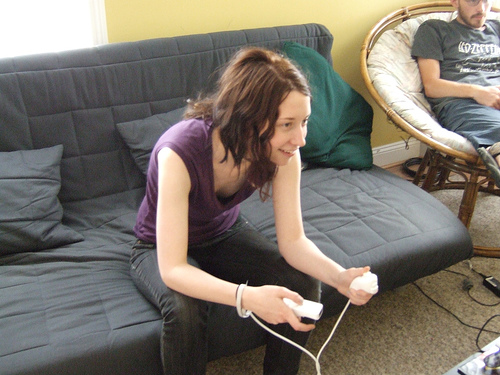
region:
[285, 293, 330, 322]
a white game controller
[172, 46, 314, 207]
a girl's brown hair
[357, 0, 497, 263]
part of a large chair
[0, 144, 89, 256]
part of a black pillow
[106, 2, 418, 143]
part of a yellow wall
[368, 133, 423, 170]
part of a white floor trim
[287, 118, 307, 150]
the nose of a girl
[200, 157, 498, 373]
a section of carpet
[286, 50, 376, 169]
part of a green pillow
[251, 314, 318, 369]
a long white cord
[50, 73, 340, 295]
Sofa is black color.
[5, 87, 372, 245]
Three pillows in couch.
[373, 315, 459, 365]
Floor is brown color.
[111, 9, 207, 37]
Wall is brown color.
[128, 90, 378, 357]
One girl is sitting in couch.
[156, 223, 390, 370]
Girl is holding wii in hand.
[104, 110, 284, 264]
Girl is wearing purple shirt.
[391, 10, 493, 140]
One boy is sitting in chair.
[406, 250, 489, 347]
Wires are black color.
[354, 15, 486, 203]
Chair is brown color.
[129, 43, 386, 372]
a girl wearing purple play the Wii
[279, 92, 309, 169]
the face of a girl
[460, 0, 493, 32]
the face of a man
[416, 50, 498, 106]
the arm of a man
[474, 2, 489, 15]
the nose of a man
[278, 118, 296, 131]
the eye of a girl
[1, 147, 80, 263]
a pillow on a couch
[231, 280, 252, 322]
a bracelet on a wrist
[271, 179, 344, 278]
the arm of a girl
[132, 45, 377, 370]
a woman sitting on a couch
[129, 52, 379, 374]
a woman playing a video game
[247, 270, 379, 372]
a Wii video game controller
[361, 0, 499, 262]
a man sitting in a chair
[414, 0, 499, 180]
a man playing a video game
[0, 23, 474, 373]
a dark grey couch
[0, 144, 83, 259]
a grey throw pillow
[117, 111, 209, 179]
a grey throw pillow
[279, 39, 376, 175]
a green throw pillow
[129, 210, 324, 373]
a pair of black jeans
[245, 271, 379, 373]
Wii game controllers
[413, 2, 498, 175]
A young man sitting in a chair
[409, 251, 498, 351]
Various cables lying on the floor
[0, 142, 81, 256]
A gray pillow on a couch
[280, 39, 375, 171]
A large green pillow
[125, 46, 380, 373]
A young woman playing a video game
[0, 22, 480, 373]
A gray couch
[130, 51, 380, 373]
A young lady in a purple tank top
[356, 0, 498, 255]
A large oval shape wicker chair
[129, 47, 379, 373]
A young lady with long dark hair sitting on a couch and playing video games.